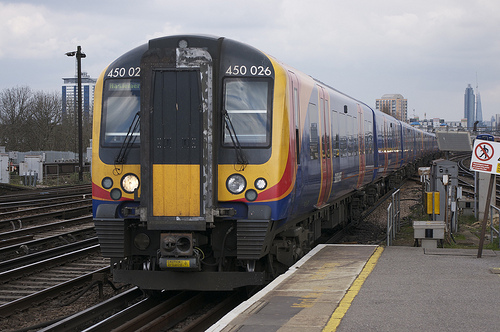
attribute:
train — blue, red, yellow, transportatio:
[90, 33, 437, 296]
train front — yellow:
[91, 36, 288, 292]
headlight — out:
[227, 174, 247, 193]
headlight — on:
[121, 172, 138, 192]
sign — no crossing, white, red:
[470, 137, 499, 176]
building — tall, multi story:
[374, 93, 408, 125]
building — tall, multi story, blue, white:
[61, 69, 95, 124]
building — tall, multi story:
[464, 81, 476, 132]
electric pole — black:
[64, 45, 86, 179]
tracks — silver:
[0, 152, 499, 331]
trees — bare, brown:
[3, 84, 93, 153]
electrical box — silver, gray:
[417, 156, 463, 232]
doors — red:
[316, 83, 333, 203]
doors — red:
[357, 106, 368, 185]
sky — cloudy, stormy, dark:
[1, 0, 499, 126]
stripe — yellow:
[322, 245, 385, 330]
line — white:
[202, 243, 381, 332]